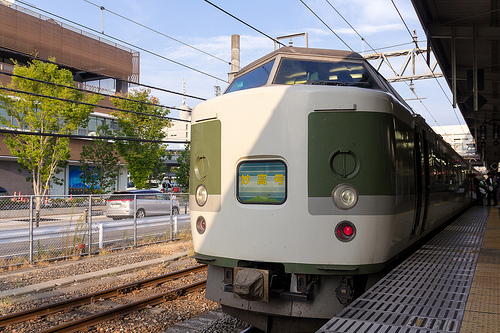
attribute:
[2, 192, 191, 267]
fence — chain link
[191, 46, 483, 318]
train — silver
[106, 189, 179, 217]
minivan — silver, parked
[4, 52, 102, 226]
tree — deciduous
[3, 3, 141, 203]
building — large, brown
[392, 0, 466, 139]
wire — suspended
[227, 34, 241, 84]
smoke stack — rusty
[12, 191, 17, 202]
cone — orange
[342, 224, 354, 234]
light — red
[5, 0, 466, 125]
sky — blue, clear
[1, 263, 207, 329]
track — metal, steel